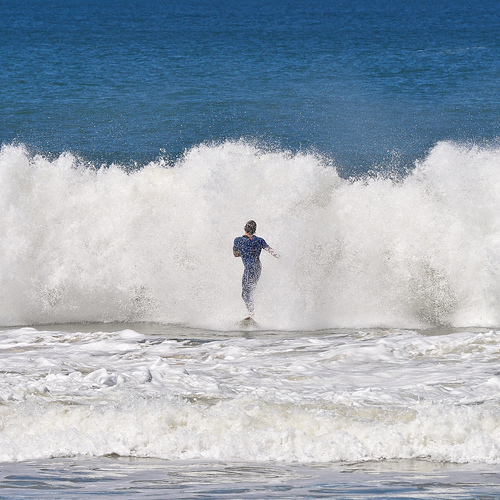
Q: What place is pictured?
A: It is an ocean.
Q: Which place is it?
A: It is an ocean.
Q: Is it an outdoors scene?
A: Yes, it is outdoors.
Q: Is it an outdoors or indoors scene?
A: It is outdoors.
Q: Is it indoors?
A: No, it is outdoors.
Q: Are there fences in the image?
A: No, there are no fences.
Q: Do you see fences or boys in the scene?
A: No, there are no fences or boys.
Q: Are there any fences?
A: No, there are no fences.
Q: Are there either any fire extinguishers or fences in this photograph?
A: No, there are no fences or fire extinguishers.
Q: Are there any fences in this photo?
A: No, there are no fences.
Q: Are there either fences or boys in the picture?
A: No, there are no fences or boys.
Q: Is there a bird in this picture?
A: No, there are no birds.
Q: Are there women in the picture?
A: No, there are no women.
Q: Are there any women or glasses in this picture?
A: No, there are no women or glasses.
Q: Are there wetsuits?
A: Yes, there is a wetsuit.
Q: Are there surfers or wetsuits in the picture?
A: Yes, there is a wetsuit.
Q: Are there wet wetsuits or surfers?
A: Yes, there is a wet wetsuit.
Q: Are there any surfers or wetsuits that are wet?
A: Yes, the wetsuit is wet.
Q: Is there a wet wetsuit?
A: Yes, there is a wet wetsuit.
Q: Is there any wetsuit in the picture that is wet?
A: Yes, there is a wetsuit that is wet.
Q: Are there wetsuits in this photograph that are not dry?
A: Yes, there is a wet wetsuit.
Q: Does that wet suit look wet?
A: Yes, the wet suit is wet.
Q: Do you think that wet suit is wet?
A: Yes, the wet suit is wet.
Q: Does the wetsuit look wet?
A: Yes, the wetsuit is wet.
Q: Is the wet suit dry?
A: No, the wet suit is wet.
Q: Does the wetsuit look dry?
A: No, the wetsuit is wet.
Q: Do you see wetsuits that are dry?
A: No, there is a wetsuit but it is wet.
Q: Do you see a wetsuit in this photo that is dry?
A: No, there is a wetsuit but it is wet.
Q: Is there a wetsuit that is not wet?
A: No, there is a wetsuit but it is wet.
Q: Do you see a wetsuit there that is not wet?
A: No, there is a wetsuit but it is wet.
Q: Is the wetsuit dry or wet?
A: The wetsuit is wet.